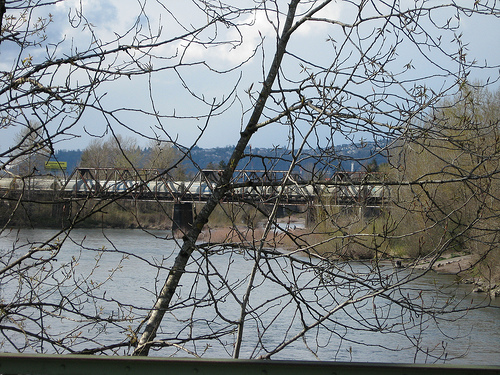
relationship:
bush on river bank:
[175, 81, 500, 257] [207, 220, 474, 254]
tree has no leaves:
[3, 10, 363, 368] [4, 1, 344, 339]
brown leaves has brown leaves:
[391, 113, 499, 230] [412, 144, 450, 171]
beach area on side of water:
[391, 251, 498, 293] [327, 272, 437, 347]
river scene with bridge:
[1, 3, 498, 369] [2, 181, 399, 226]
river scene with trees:
[1, 3, 498, 369] [1, 5, 497, 353]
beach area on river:
[391, 251, 498, 293] [2, 226, 497, 365]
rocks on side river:
[391, 250, 496, 298] [2, 226, 497, 365]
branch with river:
[0, 0, 500, 368] [2, 226, 497, 365]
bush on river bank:
[216, 79, 496, 268] [203, 216, 498, 296]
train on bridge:
[0, 176, 388, 200] [1, 178, 389, 236]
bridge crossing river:
[1, 178, 389, 236] [2, 226, 497, 365]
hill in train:
[1, 138, 398, 177] [6, 176, 409, 201]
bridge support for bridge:
[171, 202, 206, 233] [1, 173, 389, 230]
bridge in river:
[1, 173, 389, 230] [2, 226, 497, 365]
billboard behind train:
[45, 161, 68, 170] [2, 175, 409, 203]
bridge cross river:
[1, 173, 389, 230] [2, 226, 497, 365]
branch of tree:
[0, 0, 500, 368] [3, 1, 494, 361]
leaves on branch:
[296, 30, 462, 152] [3, 5, 493, 357]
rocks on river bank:
[461, 278, 500, 298] [193, 97, 495, 295]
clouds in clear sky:
[63, 10, 286, 65] [0, 0, 500, 150]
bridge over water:
[1, 173, 389, 230] [1, 227, 494, 369]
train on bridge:
[2, 175, 409, 203] [1, 173, 389, 230]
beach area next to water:
[391, 251, 498, 293] [1, 227, 494, 369]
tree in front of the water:
[131, 0, 496, 359] [5, 202, 472, 351]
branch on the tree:
[85, 100, 216, 218] [10, 5, 267, 346]